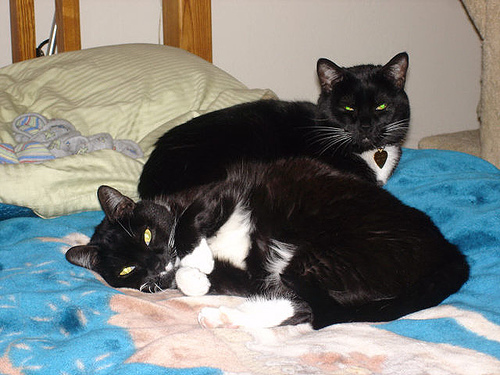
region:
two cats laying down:
[66, 50, 479, 326]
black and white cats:
[64, 51, 480, 329]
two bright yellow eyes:
[109, 220, 159, 279]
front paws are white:
[168, 245, 215, 300]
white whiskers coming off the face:
[316, 114, 418, 149]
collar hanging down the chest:
[369, 145, 394, 170]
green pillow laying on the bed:
[7, 26, 271, 160]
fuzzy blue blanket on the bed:
[5, 127, 499, 373]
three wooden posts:
[8, 3, 235, 66]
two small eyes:
[340, 100, 392, 115]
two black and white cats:
[65, 50, 470, 330]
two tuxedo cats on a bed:
[67, 51, 468, 331]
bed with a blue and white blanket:
[2, 60, 495, 372]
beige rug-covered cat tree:
[420, 5, 497, 157]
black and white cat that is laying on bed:
[64, 158, 474, 328]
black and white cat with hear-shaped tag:
[140, 50, 409, 192]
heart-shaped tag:
[372, 146, 387, 168]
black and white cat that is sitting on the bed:
[144, 54, 408, 198]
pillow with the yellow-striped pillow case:
[2, 42, 281, 210]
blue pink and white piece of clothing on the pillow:
[4, 113, 139, 161]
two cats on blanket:
[110, 82, 457, 354]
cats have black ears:
[59, 173, 129, 275]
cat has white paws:
[177, 181, 240, 320]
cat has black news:
[147, 258, 164, 275]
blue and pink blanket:
[27, 205, 103, 370]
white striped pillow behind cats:
[14, 53, 263, 142]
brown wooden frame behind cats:
[0, 2, 233, 61]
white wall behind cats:
[240, 10, 316, 84]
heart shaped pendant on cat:
[370, 136, 387, 167]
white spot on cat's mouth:
[146, 224, 173, 291]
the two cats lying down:
[65, 50, 470, 329]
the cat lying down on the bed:
[65, 184, 469, 334]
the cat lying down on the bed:
[138, 51, 410, 182]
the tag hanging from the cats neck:
[374, 149, 388, 167]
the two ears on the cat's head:
[316, 52, 408, 89]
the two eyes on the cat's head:
[342, 100, 387, 112]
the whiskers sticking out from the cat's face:
[314, 117, 408, 152]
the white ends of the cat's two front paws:
[175, 238, 213, 295]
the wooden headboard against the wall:
[0, 0, 212, 62]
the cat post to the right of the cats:
[416, 0, 498, 167]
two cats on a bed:
[71, 44, 438, 351]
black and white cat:
[76, 180, 341, 317]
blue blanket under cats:
[32, 292, 112, 364]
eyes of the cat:
[101, 220, 167, 297]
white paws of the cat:
[214, 285, 301, 338]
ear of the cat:
[82, 180, 132, 231]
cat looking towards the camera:
[38, 145, 410, 345]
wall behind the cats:
[246, 18, 308, 54]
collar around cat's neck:
[363, 138, 397, 180]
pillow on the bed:
[16, 40, 156, 194]